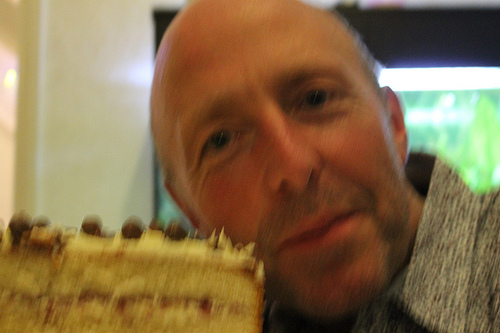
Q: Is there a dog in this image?
A: No, there are no dogs.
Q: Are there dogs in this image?
A: No, there are no dogs.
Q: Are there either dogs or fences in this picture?
A: No, there are no dogs or fences.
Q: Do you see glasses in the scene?
A: No, there are no glasses.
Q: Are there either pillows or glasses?
A: No, there are no glasses or pillows.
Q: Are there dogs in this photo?
A: No, there are no dogs.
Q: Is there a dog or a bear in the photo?
A: No, there are no dogs or bears.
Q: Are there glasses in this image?
A: No, there are no glasses.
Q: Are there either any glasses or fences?
A: No, there are no glasses or fences.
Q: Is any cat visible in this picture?
A: No, there are no cats.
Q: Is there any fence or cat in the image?
A: No, there are no cats or fences.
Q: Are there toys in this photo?
A: No, there are no toys.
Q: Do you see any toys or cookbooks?
A: No, there are no toys or cookbooks.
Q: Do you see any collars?
A: Yes, there is a collar.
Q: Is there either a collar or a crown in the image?
A: Yes, there is a collar.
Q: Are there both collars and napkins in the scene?
A: No, there is a collar but no napkins.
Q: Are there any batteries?
A: No, there are no batteries.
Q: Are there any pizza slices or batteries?
A: No, there are no batteries or pizza slices.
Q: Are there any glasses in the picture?
A: No, there are no glasses.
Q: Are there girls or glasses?
A: No, there are no glasses or girls.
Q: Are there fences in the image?
A: No, there are no fences.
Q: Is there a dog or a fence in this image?
A: No, there are no fences or dogs.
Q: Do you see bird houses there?
A: No, there are no bird houses.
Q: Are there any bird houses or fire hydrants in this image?
A: No, there are no bird houses or fire hydrants.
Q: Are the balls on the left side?
A: Yes, the balls are on the left of the image.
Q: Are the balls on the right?
A: No, the balls are on the left of the image.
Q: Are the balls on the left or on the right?
A: The balls are on the left of the image.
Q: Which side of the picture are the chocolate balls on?
A: The balls are on the left of the image.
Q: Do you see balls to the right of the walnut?
A: Yes, there are balls to the right of the walnut.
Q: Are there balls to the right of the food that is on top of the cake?
A: Yes, there are balls to the right of the walnut.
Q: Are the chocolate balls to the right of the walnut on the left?
A: Yes, the balls are to the right of the walnut.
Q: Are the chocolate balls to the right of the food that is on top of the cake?
A: Yes, the balls are to the right of the walnut.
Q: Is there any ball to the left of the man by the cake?
A: Yes, there are balls to the left of the man.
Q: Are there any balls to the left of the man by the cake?
A: Yes, there are balls to the left of the man.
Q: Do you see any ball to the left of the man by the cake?
A: Yes, there are balls to the left of the man.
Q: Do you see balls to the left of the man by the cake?
A: Yes, there are balls to the left of the man.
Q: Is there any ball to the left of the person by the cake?
A: Yes, there are balls to the left of the man.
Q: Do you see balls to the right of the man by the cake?
A: No, the balls are to the left of the man.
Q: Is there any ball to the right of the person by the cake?
A: No, the balls are to the left of the man.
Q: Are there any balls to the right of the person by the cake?
A: No, the balls are to the left of the man.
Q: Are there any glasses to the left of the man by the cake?
A: No, there are balls to the left of the man.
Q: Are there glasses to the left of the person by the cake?
A: No, there are balls to the left of the man.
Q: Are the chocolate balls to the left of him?
A: Yes, the balls are to the left of the man.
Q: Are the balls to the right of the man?
A: No, the balls are to the left of the man.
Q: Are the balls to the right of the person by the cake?
A: No, the balls are to the left of the man.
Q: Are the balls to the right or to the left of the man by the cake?
A: The balls are to the left of the man.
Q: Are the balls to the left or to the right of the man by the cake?
A: The balls are to the left of the man.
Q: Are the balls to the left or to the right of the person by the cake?
A: The balls are to the left of the man.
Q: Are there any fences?
A: No, there are no fences.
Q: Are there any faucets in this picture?
A: No, there are no faucets.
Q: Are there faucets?
A: No, there are no faucets.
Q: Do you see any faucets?
A: No, there are no faucets.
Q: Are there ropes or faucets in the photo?
A: No, there are no faucets or ropes.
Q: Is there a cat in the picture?
A: No, there are no cats.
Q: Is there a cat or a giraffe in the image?
A: No, there are no cats or giraffes.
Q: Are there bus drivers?
A: No, there are no bus drivers.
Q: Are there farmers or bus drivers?
A: No, there are no bus drivers or farmers.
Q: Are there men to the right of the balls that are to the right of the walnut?
A: Yes, there is a man to the right of the balls.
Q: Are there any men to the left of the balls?
A: No, the man is to the right of the balls.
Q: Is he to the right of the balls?
A: Yes, the man is to the right of the balls.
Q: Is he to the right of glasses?
A: No, the man is to the right of the balls.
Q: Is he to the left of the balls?
A: No, the man is to the right of the balls.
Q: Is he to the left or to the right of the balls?
A: The man is to the right of the balls.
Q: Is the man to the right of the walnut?
A: Yes, the man is to the right of the walnut.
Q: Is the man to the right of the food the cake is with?
A: Yes, the man is to the right of the walnut.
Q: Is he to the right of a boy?
A: No, the man is to the right of the walnut.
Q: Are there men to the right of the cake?
A: Yes, there is a man to the right of the cake.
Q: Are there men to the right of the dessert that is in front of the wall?
A: Yes, there is a man to the right of the cake.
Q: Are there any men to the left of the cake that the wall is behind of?
A: No, the man is to the right of the cake.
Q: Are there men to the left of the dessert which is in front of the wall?
A: No, the man is to the right of the cake.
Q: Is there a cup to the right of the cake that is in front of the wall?
A: No, there is a man to the right of the cake.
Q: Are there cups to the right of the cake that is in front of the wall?
A: No, there is a man to the right of the cake.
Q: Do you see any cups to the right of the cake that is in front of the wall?
A: No, there is a man to the right of the cake.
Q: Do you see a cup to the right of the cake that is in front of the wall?
A: No, there is a man to the right of the cake.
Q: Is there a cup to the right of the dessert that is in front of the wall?
A: No, there is a man to the right of the cake.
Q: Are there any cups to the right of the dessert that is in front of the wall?
A: No, there is a man to the right of the cake.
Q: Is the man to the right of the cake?
A: Yes, the man is to the right of the cake.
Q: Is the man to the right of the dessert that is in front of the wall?
A: Yes, the man is to the right of the cake.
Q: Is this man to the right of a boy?
A: No, the man is to the right of the cake.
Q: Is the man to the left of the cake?
A: No, the man is to the right of the cake.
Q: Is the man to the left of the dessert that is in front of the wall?
A: No, the man is to the right of the cake.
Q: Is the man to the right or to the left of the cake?
A: The man is to the right of the cake.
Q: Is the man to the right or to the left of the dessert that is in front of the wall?
A: The man is to the right of the cake.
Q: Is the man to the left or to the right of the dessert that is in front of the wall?
A: The man is to the right of the cake.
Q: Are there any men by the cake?
A: Yes, there is a man by the cake.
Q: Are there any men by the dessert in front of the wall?
A: Yes, there is a man by the cake.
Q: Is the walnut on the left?
A: Yes, the walnut is on the left of the image.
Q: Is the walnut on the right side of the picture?
A: No, the walnut is on the left of the image.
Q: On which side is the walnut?
A: The walnut is on the left of the image.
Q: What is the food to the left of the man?
A: The food is a walnut.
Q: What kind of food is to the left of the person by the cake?
A: The food is a walnut.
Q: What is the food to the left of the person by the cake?
A: The food is a walnut.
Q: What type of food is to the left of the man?
A: The food is a walnut.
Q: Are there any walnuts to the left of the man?
A: Yes, there is a walnut to the left of the man.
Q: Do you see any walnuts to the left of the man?
A: Yes, there is a walnut to the left of the man.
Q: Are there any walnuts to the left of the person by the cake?
A: Yes, there is a walnut to the left of the man.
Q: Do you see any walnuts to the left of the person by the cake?
A: Yes, there is a walnut to the left of the man.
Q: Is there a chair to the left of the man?
A: No, there is a walnut to the left of the man.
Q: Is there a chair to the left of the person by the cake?
A: No, there is a walnut to the left of the man.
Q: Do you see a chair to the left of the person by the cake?
A: No, there is a walnut to the left of the man.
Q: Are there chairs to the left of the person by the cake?
A: No, there is a walnut to the left of the man.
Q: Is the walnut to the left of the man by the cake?
A: Yes, the walnut is to the left of the man.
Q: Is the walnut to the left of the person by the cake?
A: Yes, the walnut is to the left of the man.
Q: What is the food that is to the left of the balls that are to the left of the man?
A: The food is a walnut.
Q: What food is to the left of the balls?
A: The food is a walnut.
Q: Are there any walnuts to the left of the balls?
A: Yes, there is a walnut to the left of the balls.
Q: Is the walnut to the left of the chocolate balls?
A: Yes, the walnut is to the left of the balls.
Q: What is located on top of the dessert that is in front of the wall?
A: The walnut is on top of the cake.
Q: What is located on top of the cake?
A: The walnut is on top of the cake.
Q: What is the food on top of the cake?
A: The food is a walnut.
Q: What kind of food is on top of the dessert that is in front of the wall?
A: The food is a walnut.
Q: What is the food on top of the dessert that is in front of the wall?
A: The food is a walnut.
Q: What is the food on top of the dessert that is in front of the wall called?
A: The food is a walnut.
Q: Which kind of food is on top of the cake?
A: The food is a walnut.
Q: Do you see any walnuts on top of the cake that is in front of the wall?
A: Yes, there is a walnut on top of the cake.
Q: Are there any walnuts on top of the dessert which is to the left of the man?
A: Yes, there is a walnut on top of the cake.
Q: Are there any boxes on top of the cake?
A: No, there is a walnut on top of the cake.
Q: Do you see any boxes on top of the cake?
A: No, there is a walnut on top of the cake.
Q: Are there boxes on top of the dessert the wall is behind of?
A: No, there is a walnut on top of the cake.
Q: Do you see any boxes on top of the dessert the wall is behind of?
A: No, there is a walnut on top of the cake.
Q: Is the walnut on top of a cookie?
A: No, the walnut is on top of a cake.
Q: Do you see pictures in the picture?
A: No, there are no pictures.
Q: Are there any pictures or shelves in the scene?
A: No, there are no pictures or shelves.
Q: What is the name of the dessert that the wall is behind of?
A: The dessert is a cake.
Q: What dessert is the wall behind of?
A: The wall is behind the cake.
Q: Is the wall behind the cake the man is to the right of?
A: Yes, the wall is behind the cake.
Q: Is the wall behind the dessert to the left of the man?
A: Yes, the wall is behind the cake.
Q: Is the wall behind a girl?
A: No, the wall is behind the cake.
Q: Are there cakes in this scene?
A: Yes, there is a cake.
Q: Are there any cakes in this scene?
A: Yes, there is a cake.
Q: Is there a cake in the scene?
A: Yes, there is a cake.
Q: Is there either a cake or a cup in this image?
A: Yes, there is a cake.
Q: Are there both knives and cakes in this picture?
A: No, there is a cake but no knives.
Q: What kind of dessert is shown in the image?
A: The dessert is a cake.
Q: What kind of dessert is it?
A: The dessert is a cake.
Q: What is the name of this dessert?
A: This is a cake.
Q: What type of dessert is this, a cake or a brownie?
A: This is a cake.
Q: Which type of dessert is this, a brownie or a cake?
A: This is a cake.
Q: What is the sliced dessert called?
A: The dessert is a cake.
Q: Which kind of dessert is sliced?
A: The dessert is a cake.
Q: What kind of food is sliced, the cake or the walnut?
A: The cake is sliced.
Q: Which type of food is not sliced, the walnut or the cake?
A: The walnut is not sliced.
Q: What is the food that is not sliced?
A: The food is a walnut.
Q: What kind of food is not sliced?
A: The food is a walnut.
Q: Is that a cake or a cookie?
A: That is a cake.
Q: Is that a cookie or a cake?
A: That is a cake.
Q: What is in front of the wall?
A: The cake is in front of the wall.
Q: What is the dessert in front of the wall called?
A: The dessert is a cake.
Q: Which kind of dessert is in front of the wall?
A: The dessert is a cake.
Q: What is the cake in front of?
A: The cake is in front of the wall.